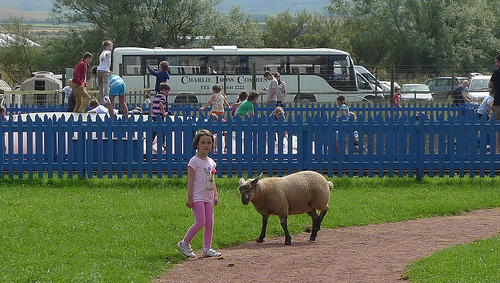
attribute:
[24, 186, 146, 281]
grass — green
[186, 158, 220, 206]
shirt — pink, short sleeved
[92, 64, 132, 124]
person — bending over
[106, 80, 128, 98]
shorts — light blue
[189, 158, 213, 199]
shirt — pink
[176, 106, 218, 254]
girl — littel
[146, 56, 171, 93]
shirt — dark blue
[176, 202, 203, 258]
leg — slightly bent back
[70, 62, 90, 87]
shirt — red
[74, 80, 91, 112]
khakis — tan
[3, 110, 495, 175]
fence — long, blue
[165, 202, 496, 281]
path — dirt 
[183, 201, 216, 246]
pants — pink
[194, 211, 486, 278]
dirt walkway — brown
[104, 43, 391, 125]
bus — white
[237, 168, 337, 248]
animal — brown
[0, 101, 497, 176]
blue fence — picket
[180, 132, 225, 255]
girl — little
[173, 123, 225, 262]
girl — little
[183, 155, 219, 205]
shirt — short sleeve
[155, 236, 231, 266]
sneakers — white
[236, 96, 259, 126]
shirt — green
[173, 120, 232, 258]
girl — young 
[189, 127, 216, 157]
hair —  short dark